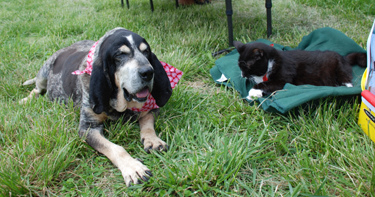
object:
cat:
[233, 40, 367, 101]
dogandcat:
[21, 22, 372, 192]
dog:
[17, 27, 183, 187]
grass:
[2, 2, 371, 193]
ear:
[89, 58, 112, 114]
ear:
[148, 51, 173, 107]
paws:
[246, 88, 263, 101]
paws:
[121, 160, 153, 187]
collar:
[262, 73, 268, 81]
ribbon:
[262, 73, 268, 81]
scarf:
[71, 40, 184, 112]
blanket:
[209, 27, 367, 113]